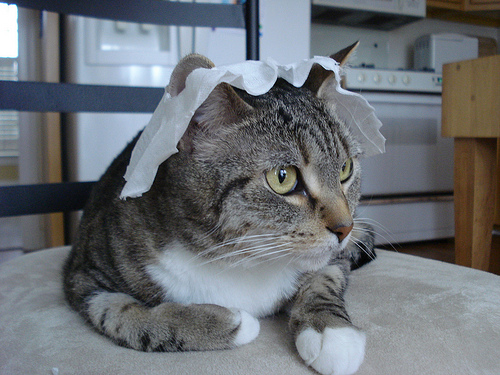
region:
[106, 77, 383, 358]
cat is grey and white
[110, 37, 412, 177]
a tissue on a cat's head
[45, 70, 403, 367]
a cat lying down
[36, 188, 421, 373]
the seat of a chair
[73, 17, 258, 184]
a refrigerator in a kitchen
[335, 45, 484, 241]
an oven in a kitchen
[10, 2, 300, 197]
the slats of a chair back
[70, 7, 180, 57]
a water dispenser in a fridge door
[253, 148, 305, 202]
a cat's right eye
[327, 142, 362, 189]
a cat's left eye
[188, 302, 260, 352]
a cat's right paw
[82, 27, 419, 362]
The cat is white, gray, and black.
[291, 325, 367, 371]
The cat has a white paw.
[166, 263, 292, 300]
Part of the cat is white.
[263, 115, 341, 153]
Part of the cat is gray with black stripes.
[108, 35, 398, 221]
The cat has a white object on his head.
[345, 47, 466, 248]
A white oven is in the background.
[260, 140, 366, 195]
The cat has yellow eyes.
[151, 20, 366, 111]
The cat has two ears.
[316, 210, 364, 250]
The cat has a pink nose.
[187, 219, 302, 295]
The cat has white whiskers.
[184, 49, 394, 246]
cat with something on head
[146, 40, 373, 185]
white thing on cat's head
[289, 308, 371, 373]
white paw of cat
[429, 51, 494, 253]
brown structure next to cat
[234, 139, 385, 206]
light eyes of cat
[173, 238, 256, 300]
white fur of cat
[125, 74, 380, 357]
multicolored cat laying down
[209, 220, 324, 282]
whiskers on cat's face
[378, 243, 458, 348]
seat of the chair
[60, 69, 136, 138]
blue back of the chair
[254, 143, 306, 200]
a yellow cat eye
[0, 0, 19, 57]
a window with sun shining in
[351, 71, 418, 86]
four control knobs on stove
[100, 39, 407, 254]
a cat with cloth on head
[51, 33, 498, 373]
a grey cat laying on chair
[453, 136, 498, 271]
a brown wooden table leg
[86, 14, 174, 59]
ice maker on front of fridge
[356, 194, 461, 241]
broiler door on stove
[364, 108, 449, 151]
oven viewing window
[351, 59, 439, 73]
black burners on stove top